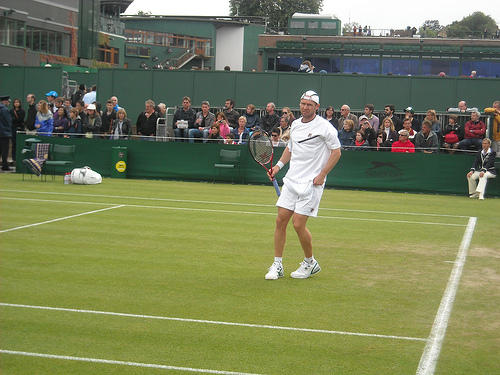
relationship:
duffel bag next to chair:
[66, 166, 110, 193] [31, 134, 91, 188]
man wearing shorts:
[261, 83, 344, 284] [276, 175, 325, 220]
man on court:
[263, 90, 342, 283] [1, 188, 484, 368]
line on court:
[107, 308, 239, 329] [1, 188, 484, 368]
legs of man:
[270, 206, 314, 265] [263, 90, 342, 283]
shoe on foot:
[263, 258, 285, 281] [261, 251, 288, 282]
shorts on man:
[272, 172, 324, 215] [263, 90, 342, 283]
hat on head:
[299, 88, 321, 104] [294, 89, 319, 119]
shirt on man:
[284, 115, 339, 184] [263, 90, 342, 283]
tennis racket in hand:
[246, 130, 282, 197] [262, 163, 279, 179]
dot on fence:
[113, 156, 128, 175] [132, 142, 191, 175]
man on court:
[263, 90, 342, 283] [39, 207, 249, 365]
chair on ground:
[28, 139, 74, 179] [13, 181, 64, 204]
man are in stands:
[390, 130, 416, 153] [65, 137, 235, 177]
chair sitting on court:
[43, 143, 75, 183] [1, 172, 500, 375]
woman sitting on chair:
[478, 147, 484, 148] [43, 143, 75, 183]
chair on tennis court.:
[43, 143, 75, 183] [438, 196, 484, 294]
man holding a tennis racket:
[263, 90, 342, 283] [248, 128, 282, 179]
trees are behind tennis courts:
[417, 12, 483, 33] [39, 187, 265, 358]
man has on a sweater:
[392, 125, 416, 156] [390, 139, 412, 152]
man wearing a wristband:
[263, 90, 342, 283] [274, 160, 286, 168]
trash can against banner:
[109, 148, 132, 181] [139, 146, 208, 178]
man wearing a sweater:
[390, 130, 416, 153] [392, 141, 412, 147]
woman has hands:
[461, 133, 499, 202] [462, 167, 482, 176]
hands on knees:
[462, 167, 482, 176] [466, 175, 484, 184]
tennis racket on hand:
[246, 119, 282, 193] [264, 166, 276, 178]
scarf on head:
[301, 88, 322, 106] [295, 86, 322, 122]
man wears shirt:
[261, 83, 344, 284] [284, 115, 339, 184]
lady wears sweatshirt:
[212, 108, 235, 138] [215, 121, 233, 135]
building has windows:
[2, 6, 83, 67] [2, 15, 74, 60]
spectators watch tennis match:
[4, 86, 498, 149] [6, 88, 495, 373]